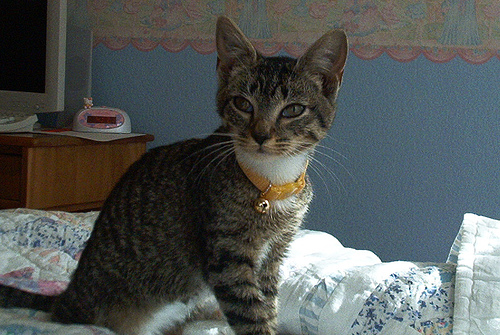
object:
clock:
[73, 97, 134, 139]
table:
[1, 130, 161, 215]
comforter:
[1, 206, 496, 333]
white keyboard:
[1, 111, 41, 135]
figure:
[56, 89, 113, 113]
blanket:
[0, 200, 499, 333]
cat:
[41, 4, 389, 326]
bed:
[5, 200, 497, 318]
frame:
[2, 9, 69, 113]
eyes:
[230, 92, 308, 119]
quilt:
[0, 180, 489, 321]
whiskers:
[176, 118, 362, 216]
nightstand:
[3, 128, 155, 213]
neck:
[221, 123, 316, 188]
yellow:
[246, 165, 308, 210]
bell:
[252, 194, 271, 216]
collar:
[234, 152, 308, 207]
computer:
[1, 5, 126, 100]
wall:
[344, 56, 495, 223]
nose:
[252, 130, 272, 145]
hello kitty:
[80, 95, 95, 109]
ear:
[290, 25, 347, 96]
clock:
[73, 104, 133, 134]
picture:
[86, 1, 499, 63]